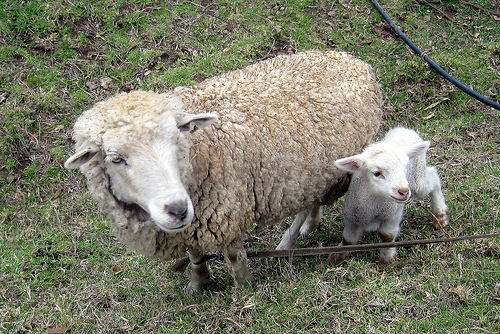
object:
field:
[3, 4, 497, 331]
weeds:
[5, 4, 87, 75]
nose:
[164, 201, 189, 221]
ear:
[176, 112, 218, 133]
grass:
[1, 5, 498, 332]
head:
[63, 91, 217, 233]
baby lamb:
[326, 126, 448, 264]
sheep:
[341, 118, 430, 256]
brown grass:
[180, 23, 186, 28]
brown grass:
[441, 148, 445, 155]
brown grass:
[406, 308, 411, 315]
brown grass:
[227, 317, 235, 325]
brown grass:
[101, 320, 106, 326]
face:
[103, 117, 194, 228]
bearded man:
[63, 49, 382, 295]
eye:
[111, 157, 126, 164]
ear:
[64, 142, 100, 170]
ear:
[334, 155, 363, 174]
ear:
[408, 141, 431, 159]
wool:
[334, 100, 381, 135]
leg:
[378, 214, 401, 258]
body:
[336, 128, 433, 257]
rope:
[172, 233, 500, 272]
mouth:
[154, 215, 194, 233]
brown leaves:
[415, 5, 487, 45]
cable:
[365, 0, 500, 111]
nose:
[398, 188, 409, 196]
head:
[334, 141, 430, 204]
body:
[186, 51, 379, 231]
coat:
[153, 49, 382, 253]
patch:
[50, 255, 151, 315]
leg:
[222, 237, 255, 286]